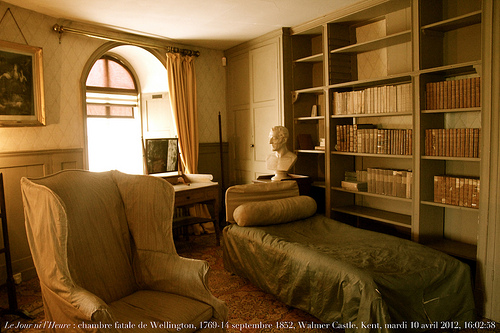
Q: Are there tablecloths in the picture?
A: No, there are no tablecloths.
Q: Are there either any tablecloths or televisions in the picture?
A: No, there are no tablecloths or televisions.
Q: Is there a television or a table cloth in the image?
A: No, there are no tablecloths or televisions.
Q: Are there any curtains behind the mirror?
A: Yes, there is a curtain behind the mirror.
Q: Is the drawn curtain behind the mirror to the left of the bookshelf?
A: Yes, the curtain is behind the mirror.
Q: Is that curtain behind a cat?
A: No, the curtain is behind the mirror.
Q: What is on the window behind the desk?
A: The curtain is on the window.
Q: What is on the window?
A: The curtain is on the window.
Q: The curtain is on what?
A: The curtain is on the window.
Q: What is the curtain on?
A: The curtain is on the window.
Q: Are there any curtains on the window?
A: Yes, there is a curtain on the window.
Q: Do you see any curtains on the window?
A: Yes, there is a curtain on the window.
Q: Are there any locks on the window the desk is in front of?
A: No, there is a curtain on the window.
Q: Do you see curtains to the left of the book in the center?
A: Yes, there is a curtain to the left of the book.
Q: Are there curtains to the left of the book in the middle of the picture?
A: Yes, there is a curtain to the left of the book.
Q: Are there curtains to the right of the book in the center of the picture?
A: No, the curtain is to the left of the book.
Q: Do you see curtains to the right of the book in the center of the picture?
A: No, the curtain is to the left of the book.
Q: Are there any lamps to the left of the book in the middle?
A: No, there is a curtain to the left of the book.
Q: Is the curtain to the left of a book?
A: Yes, the curtain is to the left of a book.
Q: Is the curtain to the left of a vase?
A: No, the curtain is to the left of a book.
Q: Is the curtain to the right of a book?
A: No, the curtain is to the left of a book.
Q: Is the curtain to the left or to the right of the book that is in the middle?
A: The curtain is to the left of the book.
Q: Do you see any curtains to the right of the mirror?
A: Yes, there is a curtain to the right of the mirror.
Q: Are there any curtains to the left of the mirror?
A: No, the curtain is to the right of the mirror.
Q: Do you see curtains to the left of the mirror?
A: No, the curtain is to the right of the mirror.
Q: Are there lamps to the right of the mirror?
A: No, there is a curtain to the right of the mirror.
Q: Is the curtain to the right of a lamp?
A: No, the curtain is to the right of a mirror.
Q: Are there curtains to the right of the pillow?
A: No, the curtain is to the left of the pillow.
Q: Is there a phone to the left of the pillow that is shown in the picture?
A: No, there is a curtain to the left of the pillow.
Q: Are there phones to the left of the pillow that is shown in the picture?
A: No, there is a curtain to the left of the pillow.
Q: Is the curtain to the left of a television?
A: No, the curtain is to the left of a pillow.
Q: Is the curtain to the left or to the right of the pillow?
A: The curtain is to the left of the pillow.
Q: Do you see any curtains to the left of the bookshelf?
A: Yes, there is a curtain to the left of the bookshelf.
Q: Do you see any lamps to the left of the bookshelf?
A: No, there is a curtain to the left of the bookshelf.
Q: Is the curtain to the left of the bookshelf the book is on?
A: Yes, the curtain is to the left of the bookshelf.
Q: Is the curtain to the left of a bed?
A: No, the curtain is to the left of the bookshelf.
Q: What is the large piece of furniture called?
A: The piece of furniture is a bookshelf.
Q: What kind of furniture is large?
A: The furniture is a bookshelf.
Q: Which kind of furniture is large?
A: The furniture is a bookshelf.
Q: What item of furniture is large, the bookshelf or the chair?
A: The bookshelf is large.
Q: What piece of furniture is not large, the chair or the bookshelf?
A: The chair is not large.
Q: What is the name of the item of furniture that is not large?
A: The piece of furniture is a chair.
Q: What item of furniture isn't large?
A: The piece of furniture is a chair.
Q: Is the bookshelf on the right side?
A: Yes, the bookshelf is on the right of the image.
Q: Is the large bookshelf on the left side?
A: No, the bookshelf is on the right of the image.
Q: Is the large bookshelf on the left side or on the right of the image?
A: The bookshelf is on the right of the image.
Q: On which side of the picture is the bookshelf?
A: The bookshelf is on the right of the image.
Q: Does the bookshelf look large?
A: Yes, the bookshelf is large.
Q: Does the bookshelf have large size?
A: Yes, the bookshelf is large.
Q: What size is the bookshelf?
A: The bookshelf is large.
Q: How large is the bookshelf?
A: The bookshelf is large.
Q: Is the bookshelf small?
A: No, the bookshelf is large.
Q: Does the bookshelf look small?
A: No, the bookshelf is large.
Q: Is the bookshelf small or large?
A: The bookshelf is large.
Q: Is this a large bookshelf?
A: Yes, this is a large bookshelf.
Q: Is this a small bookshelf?
A: No, this is a large bookshelf.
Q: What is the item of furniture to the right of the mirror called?
A: The piece of furniture is a bookshelf.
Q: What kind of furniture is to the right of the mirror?
A: The piece of furniture is a bookshelf.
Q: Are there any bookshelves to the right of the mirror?
A: Yes, there is a bookshelf to the right of the mirror.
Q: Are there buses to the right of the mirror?
A: No, there is a bookshelf to the right of the mirror.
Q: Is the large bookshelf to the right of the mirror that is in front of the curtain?
A: Yes, the bookshelf is to the right of the mirror.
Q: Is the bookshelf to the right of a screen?
A: No, the bookshelf is to the right of the mirror.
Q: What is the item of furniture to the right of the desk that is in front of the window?
A: The piece of furniture is a bookshelf.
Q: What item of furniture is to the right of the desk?
A: The piece of furniture is a bookshelf.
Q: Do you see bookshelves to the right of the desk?
A: Yes, there is a bookshelf to the right of the desk.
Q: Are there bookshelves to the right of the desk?
A: Yes, there is a bookshelf to the right of the desk.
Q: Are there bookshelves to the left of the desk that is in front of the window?
A: No, the bookshelf is to the right of the desk.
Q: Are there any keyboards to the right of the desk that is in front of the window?
A: No, there is a bookshelf to the right of the desk.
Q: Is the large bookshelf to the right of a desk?
A: Yes, the bookshelf is to the right of a desk.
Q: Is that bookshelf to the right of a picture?
A: No, the bookshelf is to the right of a desk.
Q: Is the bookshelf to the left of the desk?
A: No, the bookshelf is to the right of the desk.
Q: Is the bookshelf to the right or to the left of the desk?
A: The bookshelf is to the right of the desk.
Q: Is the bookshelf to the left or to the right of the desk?
A: The bookshelf is to the right of the desk.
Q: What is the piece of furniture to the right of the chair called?
A: The piece of furniture is a bookshelf.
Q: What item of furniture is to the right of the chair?
A: The piece of furniture is a bookshelf.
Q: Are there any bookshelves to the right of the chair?
A: Yes, there is a bookshelf to the right of the chair.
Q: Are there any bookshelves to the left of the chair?
A: No, the bookshelf is to the right of the chair.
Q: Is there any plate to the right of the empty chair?
A: No, there is a bookshelf to the right of the chair.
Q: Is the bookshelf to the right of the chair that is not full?
A: Yes, the bookshelf is to the right of the chair.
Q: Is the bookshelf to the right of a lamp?
A: No, the bookshelf is to the right of the chair.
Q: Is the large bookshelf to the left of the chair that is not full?
A: No, the bookshelf is to the right of the chair.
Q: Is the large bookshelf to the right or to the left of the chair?
A: The bookshelf is to the right of the chair.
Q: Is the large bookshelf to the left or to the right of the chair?
A: The bookshelf is to the right of the chair.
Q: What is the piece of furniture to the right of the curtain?
A: The piece of furniture is a bookshelf.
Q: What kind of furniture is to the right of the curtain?
A: The piece of furniture is a bookshelf.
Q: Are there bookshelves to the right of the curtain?
A: Yes, there is a bookshelf to the right of the curtain.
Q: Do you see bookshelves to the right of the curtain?
A: Yes, there is a bookshelf to the right of the curtain.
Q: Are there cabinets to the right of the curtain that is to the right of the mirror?
A: No, there is a bookshelf to the right of the curtain.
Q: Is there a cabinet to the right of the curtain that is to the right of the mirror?
A: No, there is a bookshelf to the right of the curtain.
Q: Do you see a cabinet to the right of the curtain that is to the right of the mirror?
A: No, there is a bookshelf to the right of the curtain.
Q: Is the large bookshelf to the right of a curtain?
A: Yes, the bookshelf is to the right of a curtain.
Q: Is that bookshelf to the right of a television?
A: No, the bookshelf is to the right of a curtain.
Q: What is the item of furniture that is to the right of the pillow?
A: The piece of furniture is a bookshelf.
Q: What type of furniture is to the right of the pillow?
A: The piece of furniture is a bookshelf.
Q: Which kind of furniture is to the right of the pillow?
A: The piece of furniture is a bookshelf.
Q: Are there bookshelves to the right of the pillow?
A: Yes, there is a bookshelf to the right of the pillow.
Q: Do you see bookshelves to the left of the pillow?
A: No, the bookshelf is to the right of the pillow.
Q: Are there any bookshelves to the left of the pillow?
A: No, the bookshelf is to the right of the pillow.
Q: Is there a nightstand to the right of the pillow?
A: No, there is a bookshelf to the right of the pillow.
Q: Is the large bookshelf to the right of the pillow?
A: Yes, the bookshelf is to the right of the pillow.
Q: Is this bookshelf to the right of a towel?
A: No, the bookshelf is to the right of the pillow.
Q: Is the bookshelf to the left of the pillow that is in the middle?
A: No, the bookshelf is to the right of the pillow.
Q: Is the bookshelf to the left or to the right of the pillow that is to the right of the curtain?
A: The bookshelf is to the right of the pillow.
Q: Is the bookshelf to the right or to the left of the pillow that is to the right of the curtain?
A: The bookshelf is to the right of the pillow.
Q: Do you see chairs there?
A: Yes, there is a chair.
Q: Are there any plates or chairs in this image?
A: Yes, there is a chair.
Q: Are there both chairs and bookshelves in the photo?
A: Yes, there are both a chair and a bookshelf.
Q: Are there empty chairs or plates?
A: Yes, there is an empty chair.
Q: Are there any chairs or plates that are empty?
A: Yes, the chair is empty.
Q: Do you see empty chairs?
A: Yes, there is an empty chair.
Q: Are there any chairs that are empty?
A: Yes, there is a chair that is empty.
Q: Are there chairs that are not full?
A: Yes, there is a empty chair.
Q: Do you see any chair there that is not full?
A: Yes, there is a empty chair.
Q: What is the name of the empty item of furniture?
A: The piece of furniture is a chair.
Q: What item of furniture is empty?
A: The piece of furniture is a chair.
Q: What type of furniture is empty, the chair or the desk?
A: The chair is empty.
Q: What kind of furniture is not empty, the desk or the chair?
A: The desk is not empty.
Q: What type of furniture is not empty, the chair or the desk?
A: The desk is not empty.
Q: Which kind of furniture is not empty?
A: The furniture is a desk.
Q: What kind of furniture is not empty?
A: The furniture is a desk.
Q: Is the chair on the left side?
A: Yes, the chair is on the left of the image.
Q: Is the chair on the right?
A: No, the chair is on the left of the image.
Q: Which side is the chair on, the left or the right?
A: The chair is on the left of the image.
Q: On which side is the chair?
A: The chair is on the left of the image.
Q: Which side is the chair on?
A: The chair is on the left of the image.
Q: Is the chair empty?
A: Yes, the chair is empty.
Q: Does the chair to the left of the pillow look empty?
A: Yes, the chair is empty.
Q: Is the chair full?
A: No, the chair is empty.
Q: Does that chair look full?
A: No, the chair is empty.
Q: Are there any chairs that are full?
A: No, there is a chair but it is empty.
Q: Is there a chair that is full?
A: No, there is a chair but it is empty.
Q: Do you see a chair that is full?
A: No, there is a chair but it is empty.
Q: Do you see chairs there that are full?
A: No, there is a chair but it is empty.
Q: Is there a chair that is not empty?
A: No, there is a chair but it is empty.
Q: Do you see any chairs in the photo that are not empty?
A: No, there is a chair but it is empty.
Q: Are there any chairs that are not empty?
A: No, there is a chair but it is empty.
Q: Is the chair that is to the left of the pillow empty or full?
A: The chair is empty.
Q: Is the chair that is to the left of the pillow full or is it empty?
A: The chair is empty.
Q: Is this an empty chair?
A: Yes, this is an empty chair.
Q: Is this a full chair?
A: No, this is an empty chair.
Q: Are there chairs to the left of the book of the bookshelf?
A: Yes, there is a chair to the left of the book.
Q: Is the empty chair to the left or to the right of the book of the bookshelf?
A: The chair is to the left of the book.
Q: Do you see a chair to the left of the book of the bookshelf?
A: Yes, there is a chair to the left of the book.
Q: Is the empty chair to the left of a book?
A: Yes, the chair is to the left of a book.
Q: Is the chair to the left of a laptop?
A: No, the chair is to the left of a book.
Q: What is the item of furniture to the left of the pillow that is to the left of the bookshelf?
A: The piece of furniture is a chair.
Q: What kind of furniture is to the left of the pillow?
A: The piece of furniture is a chair.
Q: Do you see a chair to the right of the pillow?
A: No, the chair is to the left of the pillow.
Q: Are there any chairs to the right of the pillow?
A: No, the chair is to the left of the pillow.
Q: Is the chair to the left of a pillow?
A: Yes, the chair is to the left of a pillow.